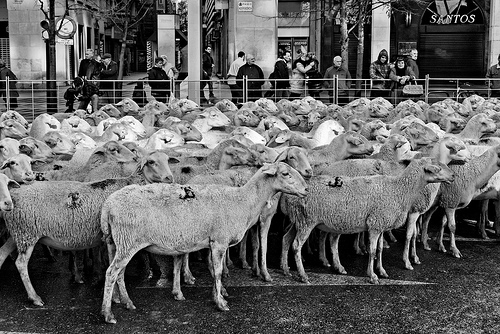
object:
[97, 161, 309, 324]
goats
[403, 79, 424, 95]
purse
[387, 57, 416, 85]
person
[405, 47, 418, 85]
person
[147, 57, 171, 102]
person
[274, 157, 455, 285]
sheep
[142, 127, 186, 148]
sheep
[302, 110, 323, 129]
sheep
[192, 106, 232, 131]
sheep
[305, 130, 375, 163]
sheep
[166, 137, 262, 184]
sheep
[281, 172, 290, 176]
goat blackeye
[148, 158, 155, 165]
goat blackeye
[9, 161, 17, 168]
goat blackeye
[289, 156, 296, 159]
goat blackeye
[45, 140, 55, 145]
goat blackeye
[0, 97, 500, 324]
sheep group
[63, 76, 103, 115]
people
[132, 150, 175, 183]
hair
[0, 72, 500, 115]
fene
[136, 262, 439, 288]
white arrow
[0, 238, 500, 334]
floor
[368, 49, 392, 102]
person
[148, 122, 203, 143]
sheep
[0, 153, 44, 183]
head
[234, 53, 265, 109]
man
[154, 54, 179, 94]
person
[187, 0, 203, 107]
pillar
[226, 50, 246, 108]
people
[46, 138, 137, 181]
sheep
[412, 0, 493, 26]
sign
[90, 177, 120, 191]
black spot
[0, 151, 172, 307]
goat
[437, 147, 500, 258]
sheep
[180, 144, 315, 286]
sheep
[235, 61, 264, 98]
jacket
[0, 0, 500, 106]
building